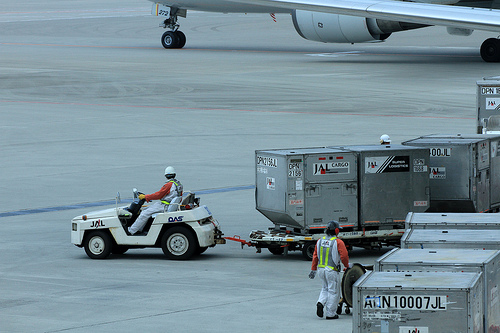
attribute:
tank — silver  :
[347, 210, 497, 330]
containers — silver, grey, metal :
[255, 147, 358, 232]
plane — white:
[177, 0, 499, 61]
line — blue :
[2, 181, 254, 216]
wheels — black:
[160, 29, 187, 50]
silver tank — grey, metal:
[353, 270, 484, 332]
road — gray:
[2, 2, 499, 332]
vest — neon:
[316, 235, 342, 271]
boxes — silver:
[352, 211, 497, 331]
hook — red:
[220, 233, 254, 246]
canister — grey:
[328, 144, 433, 228]